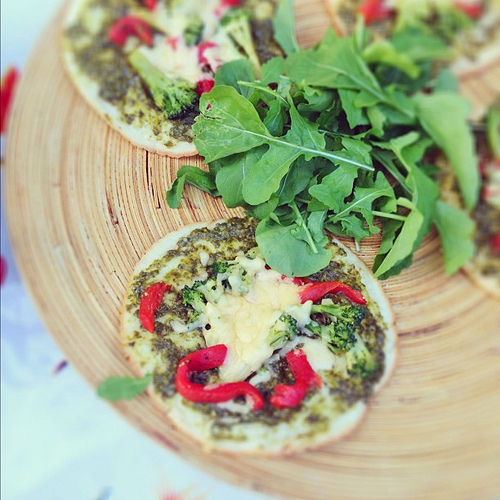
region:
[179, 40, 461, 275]
spring mix lettuce leaves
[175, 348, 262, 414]
sliver of red pepper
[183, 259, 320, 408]
melted mozzarella on a bagel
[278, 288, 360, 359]
a small piece of broccoli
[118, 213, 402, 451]
a piece of bread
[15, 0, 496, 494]
a light brown wooden divet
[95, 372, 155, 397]
a small green lettuce leaf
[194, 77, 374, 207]
a large green lettuce leaf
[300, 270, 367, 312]
a twisted sliver of pepper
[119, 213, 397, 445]
pesto, cheese, and peppers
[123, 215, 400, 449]
A TINY FLAT BREAD APPETIZER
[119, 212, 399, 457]
BREAD WITH PEPPER, BROCCOLI, SAUCE, AND CHEESE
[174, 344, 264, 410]
A SLICE OF RED BELL PEPPER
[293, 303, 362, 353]
A TINY CROWN OF BROCCOLI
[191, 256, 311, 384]
CLUSTER OF MELTED CHEESE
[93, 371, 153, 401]
A BLURRY PIECE OF GREEN LEAFY VEG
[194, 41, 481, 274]
A HANDFUL OF LEAFY GREENS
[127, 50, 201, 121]
GREEN PIECE OF BROCCOLI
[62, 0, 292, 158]
HEALTHY LOOKING PIZZA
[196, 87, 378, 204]
LEAFY GREEN ARUGULA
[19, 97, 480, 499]
a wooden plate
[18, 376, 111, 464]
the white table under the plate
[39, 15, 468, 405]
a plate of food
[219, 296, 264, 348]
cheese on the food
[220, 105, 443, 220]
yellow leaves on the plate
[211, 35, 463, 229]
lettuce on the plate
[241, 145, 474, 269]
chopped up lettuce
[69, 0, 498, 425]
a plate of colorful food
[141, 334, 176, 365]
sauce on the food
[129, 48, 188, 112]
broccoli on the food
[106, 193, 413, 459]
round piece of food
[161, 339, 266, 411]
red sliver of food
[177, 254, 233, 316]
broccoli bits on top of food item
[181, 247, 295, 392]
melted cheese on surface of food item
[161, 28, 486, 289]
pile of green lettuce on surface of wooden plate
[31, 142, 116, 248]
curved line pattern on wicker plate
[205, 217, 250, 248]
green seasoning on food item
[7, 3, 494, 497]
round wicker plate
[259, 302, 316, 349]
melted cheese and broccoli bits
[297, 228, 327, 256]
green stem of lettuce leaf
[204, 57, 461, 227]
the leaves are green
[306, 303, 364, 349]
the broccoli is green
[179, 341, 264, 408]
the pepper is red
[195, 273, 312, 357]
the cheese is in the center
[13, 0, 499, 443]
the leaves are at the center of the dish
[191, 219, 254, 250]
the sauce is green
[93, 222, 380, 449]
the leaf is on the edge of the dish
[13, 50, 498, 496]
the dish is brown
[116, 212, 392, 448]
the food is green red and white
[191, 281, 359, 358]
the cheese is on top of the broccoli